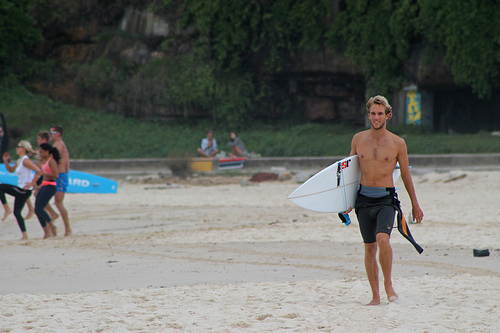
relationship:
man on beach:
[342, 94, 424, 305] [0, 167, 499, 331]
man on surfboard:
[342, 94, 424, 305] [273, 147, 356, 219]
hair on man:
[363, 89, 398, 131] [338, 86, 428, 311]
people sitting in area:
[225, 131, 249, 158] [150, 147, 297, 165]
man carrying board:
[338, 86, 428, 311] [286, 154, 413, 213]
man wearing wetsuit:
[342, 94, 424, 305] [355, 186, 400, 238]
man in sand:
[342, 94, 424, 305] [288, 295, 297, 302]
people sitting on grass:
[199, 133, 253, 156] [73, 111, 133, 156]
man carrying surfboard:
[338, 86, 428, 311] [292, 153, 353, 211]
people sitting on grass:
[195, 128, 249, 158] [195, 128, 251, 157]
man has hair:
[338, 86, 428, 311] [364, 93, 387, 105]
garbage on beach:
[466, 247, 499, 268] [4, 250, 336, 331]